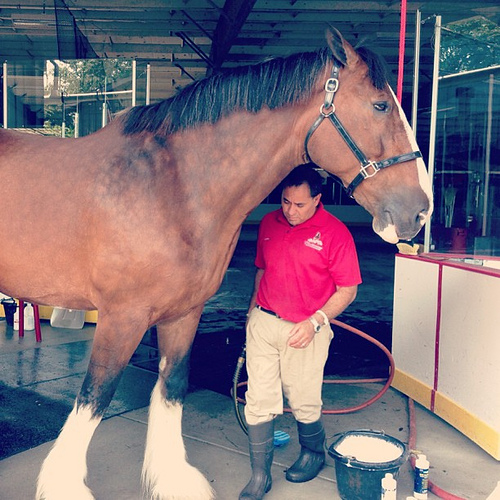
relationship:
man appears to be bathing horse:
[237, 168, 362, 499] [22, 40, 432, 497]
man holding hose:
[237, 162, 362, 497] [231, 317, 396, 435]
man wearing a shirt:
[237, 162, 362, 497] [248, 204, 365, 328]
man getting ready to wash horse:
[237, 162, 362, 497] [22, 40, 432, 497]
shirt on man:
[263, 220, 341, 291] [275, 163, 320, 233]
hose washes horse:
[229, 317, 395, 415] [233, 45, 421, 214]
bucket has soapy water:
[320, 423, 410, 498] [341, 432, 400, 462]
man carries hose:
[237, 168, 362, 499] [334, 315, 408, 475]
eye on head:
[371, 99, 388, 116] [294, 24, 439, 247]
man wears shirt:
[237, 162, 362, 497] [255, 202, 362, 322]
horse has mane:
[22, 40, 432, 497] [109, 44, 384, 131]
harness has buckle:
[298, 61, 422, 201] [316, 75, 339, 117]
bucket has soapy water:
[320, 423, 410, 498] [336, 432, 403, 462]